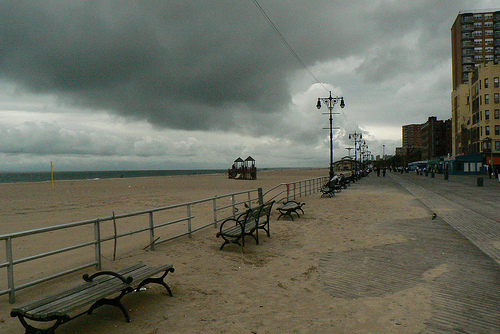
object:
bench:
[276, 200, 306, 221]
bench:
[319, 178, 340, 198]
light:
[315, 97, 345, 110]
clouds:
[1, 0, 498, 145]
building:
[402, 13, 499, 172]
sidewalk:
[298, 135, 498, 320]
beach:
[0, 168, 493, 331]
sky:
[2, 0, 499, 164]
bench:
[216, 200, 276, 252]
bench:
[11, 262, 175, 333]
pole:
[50, 161, 54, 190]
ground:
[0, 165, 498, 332]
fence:
[0, 177, 335, 306]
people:
[376, 166, 423, 177]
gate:
[100, 212, 157, 264]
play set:
[227, 156, 257, 180]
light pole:
[330, 91, 335, 178]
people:
[323, 173, 346, 187]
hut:
[227, 156, 256, 180]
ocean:
[0, 169, 214, 184]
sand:
[0, 168, 442, 333]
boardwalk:
[1, 165, 498, 332]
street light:
[315, 97, 344, 110]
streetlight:
[315, 91, 345, 179]